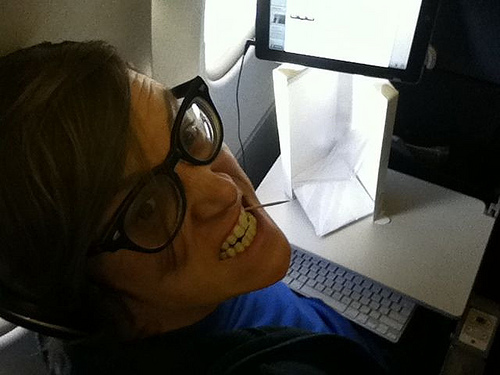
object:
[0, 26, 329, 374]
guy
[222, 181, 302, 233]
pick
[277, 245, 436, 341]
keyboard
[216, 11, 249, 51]
window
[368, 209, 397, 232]
table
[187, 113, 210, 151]
glass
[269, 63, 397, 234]
book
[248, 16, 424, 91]
screen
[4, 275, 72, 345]
phone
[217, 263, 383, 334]
shirt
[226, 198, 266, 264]
teeth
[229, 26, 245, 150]
cord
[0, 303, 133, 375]
chair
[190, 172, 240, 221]
nose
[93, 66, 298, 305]
face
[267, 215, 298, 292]
chin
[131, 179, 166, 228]
eye